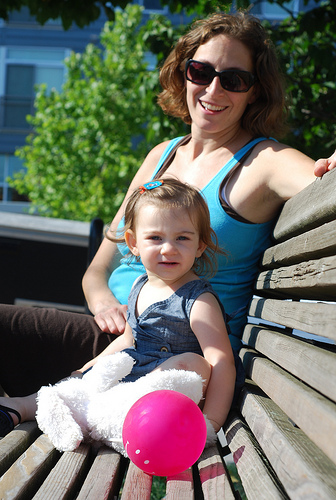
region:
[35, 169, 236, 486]
The little girl has a stuffed animal.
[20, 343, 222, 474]
The stuffed animal is white.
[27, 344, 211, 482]
The stuffed animal is fluffy.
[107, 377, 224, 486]
The girl has a balloon.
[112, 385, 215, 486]
The balloon is red.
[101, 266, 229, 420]
The girl is wearing a blue jumper.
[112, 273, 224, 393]
The blue jumper is denim.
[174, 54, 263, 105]
The woman is wearing dark glasses.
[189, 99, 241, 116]
The woman is smiling.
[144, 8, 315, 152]
The woman has dark hair.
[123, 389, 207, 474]
a small pink and white balloon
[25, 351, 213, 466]
a white stuffed animal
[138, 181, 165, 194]
a girl's barrette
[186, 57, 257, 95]
large dark black sunglasses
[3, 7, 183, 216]
part of a large green tree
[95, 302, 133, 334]
the hand of a woman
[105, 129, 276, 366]
a woman's tank top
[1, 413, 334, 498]
part of a wooden bench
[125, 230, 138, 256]
the ear of a girl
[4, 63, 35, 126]
the window of a building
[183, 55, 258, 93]
black glasses on the woman's face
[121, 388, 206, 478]
pink ball on the bench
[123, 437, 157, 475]
white smiley face on the pink ball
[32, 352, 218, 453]
white stuffed animal on the bench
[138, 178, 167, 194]
orange and blue clip in the girl's hair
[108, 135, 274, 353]
blue tank top on the woman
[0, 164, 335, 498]
brown wooden bench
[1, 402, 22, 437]
girl wearing a black sandal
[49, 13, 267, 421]
a woman sitting with her daughter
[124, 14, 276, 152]
the head of an adult woman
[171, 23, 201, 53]
the hair of an adult woman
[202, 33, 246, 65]
the forehead of an adult woman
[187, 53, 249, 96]
the sunglasses of an adult woman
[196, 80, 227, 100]
the nose of an adult woman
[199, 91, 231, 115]
the mouth of an adult woman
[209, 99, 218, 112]
the teeth of an adult woman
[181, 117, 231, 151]
the neck of an adult woman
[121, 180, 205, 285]
the head of a little baby girl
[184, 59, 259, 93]
the sunglasses on the woman's face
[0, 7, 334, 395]
the woman sitting on the bench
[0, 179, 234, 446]
the toddler sitting next o the woman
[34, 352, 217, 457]
the stuffed animal to the toddler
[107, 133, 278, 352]
the tank top on the woman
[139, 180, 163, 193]
the hairpin in the toddler's hair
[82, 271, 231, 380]
the dress on the toddler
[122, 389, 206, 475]
the balloon near the toddler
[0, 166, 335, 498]
the bench the woman and toddler is sitting on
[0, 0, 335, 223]
the tree branches in the background